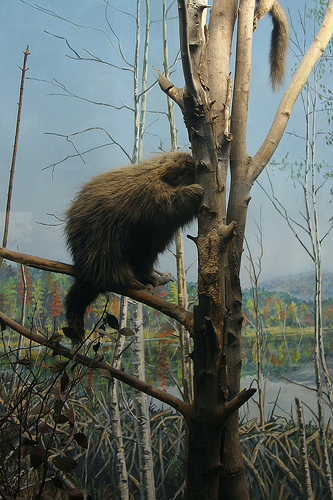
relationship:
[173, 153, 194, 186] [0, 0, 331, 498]
face against tree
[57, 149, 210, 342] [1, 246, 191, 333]
beaver on branch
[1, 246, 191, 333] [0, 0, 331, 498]
branch on tree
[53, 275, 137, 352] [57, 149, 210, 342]
tail on beaver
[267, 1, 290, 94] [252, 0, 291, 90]
tail on beaver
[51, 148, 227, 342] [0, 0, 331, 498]
animal in tree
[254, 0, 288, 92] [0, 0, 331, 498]
animal in tree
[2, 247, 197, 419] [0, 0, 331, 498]
branches on tree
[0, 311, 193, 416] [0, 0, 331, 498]
branch on tree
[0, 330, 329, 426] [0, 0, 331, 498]
lake behind tree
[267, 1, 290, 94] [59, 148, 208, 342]
tail on animal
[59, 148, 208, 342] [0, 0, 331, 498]
animal at top of tree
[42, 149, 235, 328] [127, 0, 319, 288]
beaver in tree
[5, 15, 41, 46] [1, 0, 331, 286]
cloud in sky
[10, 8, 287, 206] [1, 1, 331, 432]
clouds in sky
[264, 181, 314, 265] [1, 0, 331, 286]
clouds in sky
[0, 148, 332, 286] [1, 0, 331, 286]
clouds in sky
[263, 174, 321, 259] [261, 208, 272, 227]
clouds in sky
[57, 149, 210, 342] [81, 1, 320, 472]
beaver standing tree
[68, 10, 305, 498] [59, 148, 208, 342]
tree with animal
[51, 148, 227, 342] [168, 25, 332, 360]
animal at top tree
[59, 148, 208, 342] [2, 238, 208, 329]
animal standing branch